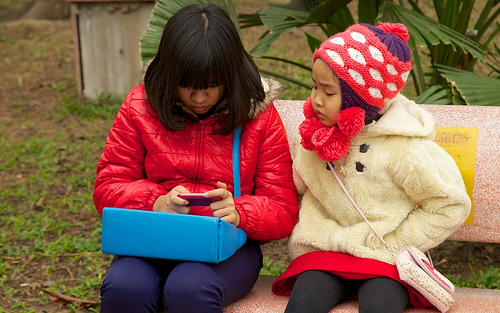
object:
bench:
[223, 275, 499, 313]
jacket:
[285, 92, 472, 267]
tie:
[298, 97, 365, 161]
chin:
[316, 117, 338, 126]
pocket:
[365, 228, 396, 251]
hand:
[380, 231, 402, 255]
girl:
[93, 4, 299, 313]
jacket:
[93, 57, 299, 241]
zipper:
[188, 120, 206, 215]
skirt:
[282, 269, 411, 312]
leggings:
[280, 270, 410, 312]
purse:
[101, 128, 247, 264]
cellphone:
[176, 193, 221, 206]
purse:
[325, 161, 458, 313]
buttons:
[356, 161, 364, 172]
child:
[272, 21, 471, 313]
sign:
[421, 126, 480, 225]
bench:
[273, 99, 500, 243]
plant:
[140, 1, 499, 108]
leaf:
[0, 181, 84, 309]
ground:
[0, 86, 95, 178]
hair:
[144, 3, 266, 136]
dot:
[347, 47, 368, 65]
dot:
[369, 67, 384, 82]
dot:
[350, 32, 367, 44]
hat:
[298, 21, 411, 161]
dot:
[400, 69, 410, 82]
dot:
[330, 37, 345, 46]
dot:
[386, 82, 398, 92]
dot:
[325, 49, 346, 68]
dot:
[347, 68, 365, 86]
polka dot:
[368, 86, 383, 99]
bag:
[394, 246, 455, 313]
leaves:
[141, 0, 500, 106]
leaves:
[137, 3, 498, 87]